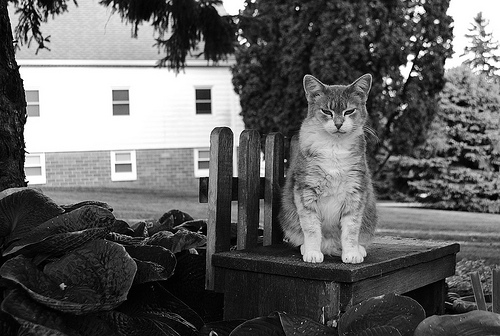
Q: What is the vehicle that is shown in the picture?
A: The vehicle is a car.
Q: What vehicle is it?
A: The vehicle is a car.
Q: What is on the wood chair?
A: The car is on the chair.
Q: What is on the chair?
A: The car is on the chair.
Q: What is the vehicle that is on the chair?
A: The vehicle is a car.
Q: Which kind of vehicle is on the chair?
A: The vehicle is a car.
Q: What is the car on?
A: The car is on the chair.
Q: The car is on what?
A: The car is on the chair.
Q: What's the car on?
A: The car is on the chair.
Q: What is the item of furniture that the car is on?
A: The piece of furniture is a chair.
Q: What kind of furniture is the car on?
A: The car is on the chair.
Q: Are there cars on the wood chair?
A: Yes, there is a car on the chair.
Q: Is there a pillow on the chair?
A: No, there is a car on the chair.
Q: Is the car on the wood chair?
A: Yes, the car is on the chair.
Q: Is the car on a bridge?
A: No, the car is on the chair.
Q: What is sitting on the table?
A: The car is sitting on the table.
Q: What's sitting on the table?
A: The car is sitting on the table.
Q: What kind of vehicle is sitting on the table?
A: The vehicle is a car.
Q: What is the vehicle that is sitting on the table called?
A: The vehicle is a car.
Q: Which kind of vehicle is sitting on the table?
A: The vehicle is a car.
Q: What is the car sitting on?
A: The car is sitting on the table.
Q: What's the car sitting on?
A: The car is sitting on the table.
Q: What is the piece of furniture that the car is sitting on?
A: The piece of furniture is a table.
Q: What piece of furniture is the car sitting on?
A: The car is sitting on the table.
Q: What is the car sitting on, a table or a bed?
A: The car is sitting on a table.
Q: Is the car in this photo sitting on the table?
A: Yes, the car is sitting on the table.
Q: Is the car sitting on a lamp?
A: No, the car is sitting on the table.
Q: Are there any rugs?
A: No, there are no rugs.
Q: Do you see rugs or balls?
A: No, there are no rugs or balls.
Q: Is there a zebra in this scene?
A: No, there are no zebras.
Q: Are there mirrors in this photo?
A: No, there are no mirrors.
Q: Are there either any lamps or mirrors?
A: No, there are no mirrors or lamps.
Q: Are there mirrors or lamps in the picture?
A: No, there are no mirrors or lamps.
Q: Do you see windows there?
A: Yes, there is a window.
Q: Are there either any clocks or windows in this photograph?
A: Yes, there is a window.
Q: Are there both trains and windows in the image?
A: No, there is a window but no trains.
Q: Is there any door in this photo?
A: No, there are no doors.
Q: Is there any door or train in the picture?
A: No, there are no doors or trains.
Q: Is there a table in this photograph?
A: Yes, there is a table.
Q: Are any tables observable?
A: Yes, there is a table.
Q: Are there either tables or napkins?
A: Yes, there is a table.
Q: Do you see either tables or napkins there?
A: Yes, there is a table.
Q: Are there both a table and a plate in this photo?
A: No, there is a table but no plates.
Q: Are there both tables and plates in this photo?
A: No, there is a table but no plates.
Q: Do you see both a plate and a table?
A: No, there is a table but no plates.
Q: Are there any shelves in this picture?
A: No, there are no shelves.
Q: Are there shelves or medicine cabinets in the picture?
A: No, there are no shelves or medicine cabinets.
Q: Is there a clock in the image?
A: No, there are no clocks.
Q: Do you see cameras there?
A: Yes, there is a camera.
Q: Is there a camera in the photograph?
A: Yes, there is a camera.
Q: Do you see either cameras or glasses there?
A: Yes, there is a camera.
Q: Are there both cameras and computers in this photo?
A: No, there is a camera but no computers.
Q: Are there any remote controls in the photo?
A: No, there are no remote controls.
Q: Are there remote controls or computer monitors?
A: No, there are no remote controls or computer monitors.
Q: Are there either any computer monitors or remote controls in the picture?
A: No, there are no remote controls or computer monitors.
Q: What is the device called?
A: The device is a camera.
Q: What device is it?
A: The device is a camera.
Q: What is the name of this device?
A: That is a camera.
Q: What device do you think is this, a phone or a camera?
A: That is a camera.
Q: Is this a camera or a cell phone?
A: This is a camera.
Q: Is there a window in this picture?
A: Yes, there is a window.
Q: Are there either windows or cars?
A: Yes, there is a window.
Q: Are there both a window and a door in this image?
A: No, there is a window but no doors.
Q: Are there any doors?
A: No, there are no doors.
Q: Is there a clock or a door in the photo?
A: No, there are no doors or clocks.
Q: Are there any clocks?
A: No, there are no clocks.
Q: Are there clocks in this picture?
A: No, there are no clocks.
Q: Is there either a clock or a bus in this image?
A: No, there are no clocks or buses.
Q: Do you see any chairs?
A: Yes, there is a chair.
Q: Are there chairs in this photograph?
A: Yes, there is a chair.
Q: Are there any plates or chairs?
A: Yes, there is a chair.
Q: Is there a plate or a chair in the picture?
A: Yes, there is a chair.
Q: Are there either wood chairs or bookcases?
A: Yes, there is a wood chair.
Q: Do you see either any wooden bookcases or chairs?
A: Yes, there is a wood chair.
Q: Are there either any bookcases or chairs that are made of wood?
A: Yes, the chair is made of wood.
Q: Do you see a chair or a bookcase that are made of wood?
A: Yes, the chair is made of wood.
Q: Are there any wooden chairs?
A: Yes, there is a wood chair.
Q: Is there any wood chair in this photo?
A: Yes, there is a wood chair.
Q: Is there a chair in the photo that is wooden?
A: Yes, there is a chair that is wooden.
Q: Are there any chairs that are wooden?
A: Yes, there is a chair that is wooden.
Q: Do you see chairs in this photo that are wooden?
A: Yes, there is a chair that is wooden.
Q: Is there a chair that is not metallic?
A: Yes, there is a wooden chair.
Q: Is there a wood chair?
A: Yes, there is a chair that is made of wood.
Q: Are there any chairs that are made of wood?
A: Yes, there is a chair that is made of wood.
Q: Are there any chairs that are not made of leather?
A: Yes, there is a chair that is made of wood.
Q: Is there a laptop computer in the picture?
A: No, there are no laptops.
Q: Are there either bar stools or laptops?
A: No, there are no laptops or bar stools.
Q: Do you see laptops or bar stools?
A: No, there are no laptops or bar stools.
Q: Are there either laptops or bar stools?
A: No, there are no laptops or bar stools.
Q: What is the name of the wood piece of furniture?
A: The piece of furniture is a chair.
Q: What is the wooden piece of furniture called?
A: The piece of furniture is a chair.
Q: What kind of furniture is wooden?
A: The furniture is a chair.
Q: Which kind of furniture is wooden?
A: The furniture is a chair.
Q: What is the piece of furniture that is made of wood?
A: The piece of furniture is a chair.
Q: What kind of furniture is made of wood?
A: The furniture is a chair.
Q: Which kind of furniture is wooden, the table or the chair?
A: The chair is wooden.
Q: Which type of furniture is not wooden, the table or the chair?
A: The table is not wooden.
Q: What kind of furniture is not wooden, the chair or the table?
A: The table is not wooden.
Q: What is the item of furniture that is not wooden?
A: The piece of furniture is a table.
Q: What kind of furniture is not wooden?
A: The furniture is a table.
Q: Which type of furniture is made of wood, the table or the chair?
A: The chair is made of wood.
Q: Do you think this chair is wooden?
A: Yes, the chair is wooden.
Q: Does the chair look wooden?
A: Yes, the chair is wooden.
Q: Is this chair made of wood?
A: Yes, the chair is made of wood.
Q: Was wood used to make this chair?
A: Yes, the chair is made of wood.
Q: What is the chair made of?
A: The chair is made of wood.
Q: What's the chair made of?
A: The chair is made of wood.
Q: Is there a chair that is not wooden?
A: No, there is a chair but it is wooden.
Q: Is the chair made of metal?
A: No, the chair is made of wood.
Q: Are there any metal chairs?
A: No, there is a chair but it is made of wood.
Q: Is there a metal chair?
A: No, there is a chair but it is made of wood.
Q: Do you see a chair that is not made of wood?
A: No, there is a chair but it is made of wood.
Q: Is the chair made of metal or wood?
A: The chair is made of wood.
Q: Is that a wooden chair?
A: Yes, that is a wooden chair.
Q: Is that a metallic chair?
A: No, that is a wooden chair.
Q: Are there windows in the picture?
A: Yes, there is a window.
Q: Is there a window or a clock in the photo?
A: Yes, there is a window.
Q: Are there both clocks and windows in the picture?
A: No, there is a window but no clocks.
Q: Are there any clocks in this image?
A: No, there are no clocks.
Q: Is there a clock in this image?
A: No, there are no clocks.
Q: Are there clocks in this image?
A: No, there are no clocks.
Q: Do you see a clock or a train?
A: No, there are no clocks or trains.